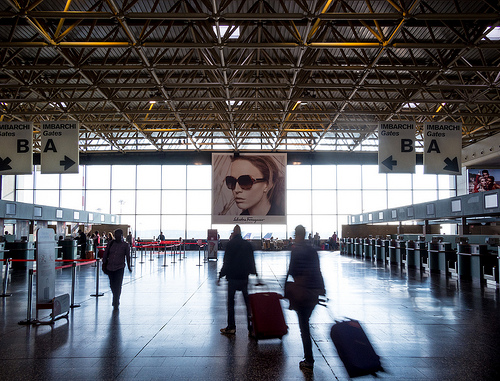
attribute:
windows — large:
[51, 139, 454, 254]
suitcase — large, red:
[228, 273, 314, 367]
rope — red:
[9, 234, 191, 294]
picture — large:
[203, 141, 290, 231]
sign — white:
[361, 96, 492, 183]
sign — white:
[426, 115, 462, 187]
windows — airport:
[12, 161, 472, 240]